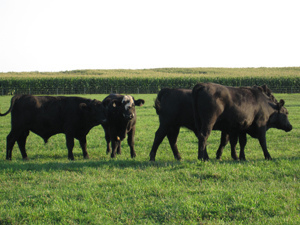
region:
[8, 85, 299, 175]
four cows on grass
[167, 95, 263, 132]
cows have black fur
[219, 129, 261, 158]
cows have dark legs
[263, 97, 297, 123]
cows have dark ears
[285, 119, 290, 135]
cows have dark noses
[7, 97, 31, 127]
cow has long tail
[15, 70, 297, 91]
tall green corn stalks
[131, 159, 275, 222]
grass is green and thick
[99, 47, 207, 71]
sky is bright and white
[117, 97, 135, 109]
white spot on cow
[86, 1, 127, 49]
white clouds in blue sky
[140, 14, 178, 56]
white clouds in blue sky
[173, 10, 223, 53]
white clouds in blue sky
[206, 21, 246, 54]
white clouds in blue sky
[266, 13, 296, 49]
white clouds in blue sky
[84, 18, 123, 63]
white clouds in blue sky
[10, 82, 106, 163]
black cow in field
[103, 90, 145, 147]
black cow in field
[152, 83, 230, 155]
black cow in field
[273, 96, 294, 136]
head of a black cow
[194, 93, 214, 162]
rear leg of a black cow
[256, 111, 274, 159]
front leg of black cow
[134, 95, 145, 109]
ear of a black cow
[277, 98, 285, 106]
ear of a black cow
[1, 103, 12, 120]
tail of a black cow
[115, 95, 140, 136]
head of a black cow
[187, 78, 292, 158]
black cow on grass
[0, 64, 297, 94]
stalks of tall corn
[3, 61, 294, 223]
cows in a pasture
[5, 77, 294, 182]
cows in the pasture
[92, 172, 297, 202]
green grass in the field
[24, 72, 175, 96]
corn growing behind the cows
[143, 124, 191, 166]
back legs of a cow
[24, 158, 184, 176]
shadows in the ground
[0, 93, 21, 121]
tail of a cow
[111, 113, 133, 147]
head of a cow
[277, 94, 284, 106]
right ear of a cow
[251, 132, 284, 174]
front leg of a cow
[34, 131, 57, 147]
udder of a cow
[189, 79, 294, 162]
large cow in a field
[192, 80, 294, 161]
large black cow in a field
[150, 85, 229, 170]
part of a cow in a field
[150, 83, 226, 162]
part of a large black cow in a field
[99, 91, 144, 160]
black cow with white face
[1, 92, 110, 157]
black cow next to the cow with white on it's face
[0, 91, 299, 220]
grassy field where cowss are grazing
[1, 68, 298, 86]
corn field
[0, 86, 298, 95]
fence seperating grassy area from corn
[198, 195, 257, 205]
grassy area